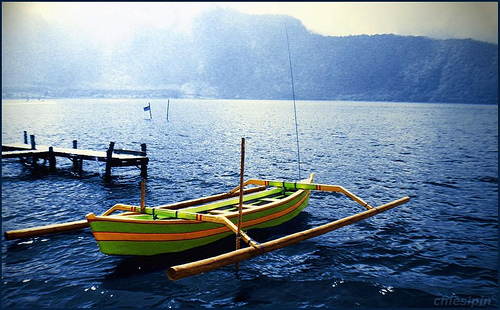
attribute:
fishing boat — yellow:
[82, 170, 335, 270]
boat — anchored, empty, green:
[102, 178, 343, 271]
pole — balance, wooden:
[240, 139, 244, 237]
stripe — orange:
[106, 223, 296, 227]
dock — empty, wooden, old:
[0, 143, 155, 198]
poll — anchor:
[224, 141, 259, 246]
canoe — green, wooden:
[75, 165, 331, 241]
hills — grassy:
[35, 28, 487, 100]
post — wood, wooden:
[97, 150, 117, 182]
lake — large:
[14, 102, 456, 269]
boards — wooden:
[212, 195, 276, 212]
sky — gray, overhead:
[268, 7, 495, 35]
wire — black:
[281, 26, 305, 185]